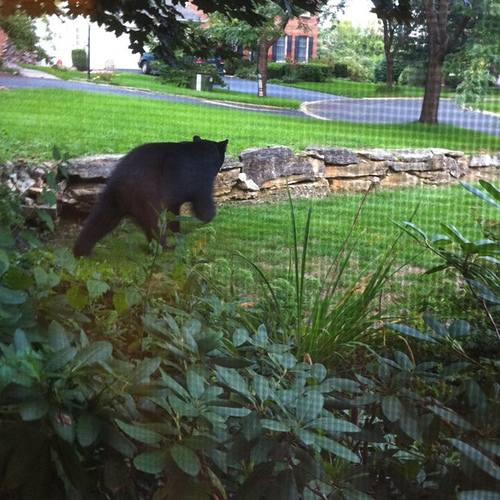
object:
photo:
[0, 0, 499, 498]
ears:
[218, 138, 228, 153]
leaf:
[0, 144, 500, 500]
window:
[295, 35, 313, 62]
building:
[167, 0, 319, 63]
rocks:
[0, 143, 500, 229]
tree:
[0, 0, 500, 125]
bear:
[73, 134, 229, 256]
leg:
[190, 189, 217, 221]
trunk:
[419, 0, 449, 125]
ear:
[193, 135, 202, 142]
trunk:
[257, 38, 268, 97]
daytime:
[0, 0, 500, 500]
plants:
[0, 0, 500, 500]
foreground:
[0, 129, 500, 500]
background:
[0, 0, 499, 158]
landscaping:
[0, 0, 500, 500]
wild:
[0, 86, 500, 500]